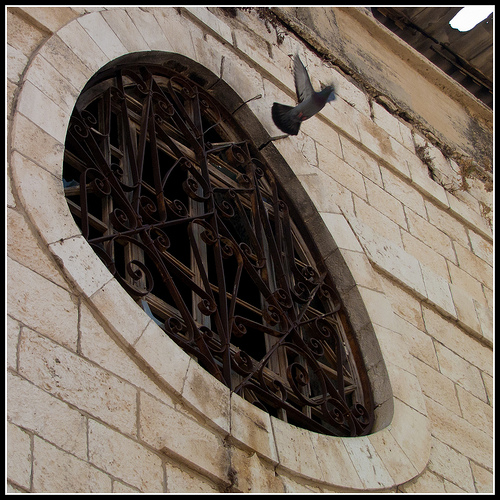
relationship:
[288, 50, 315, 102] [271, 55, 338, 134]
wing belonging to pigeon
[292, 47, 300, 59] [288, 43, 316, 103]
tip belonging to wing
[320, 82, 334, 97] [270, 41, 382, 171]
head belonging to pigeon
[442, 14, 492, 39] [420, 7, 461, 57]
hole in rood tile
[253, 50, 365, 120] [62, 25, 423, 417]
bird flying away window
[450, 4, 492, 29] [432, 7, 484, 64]
sky through a tile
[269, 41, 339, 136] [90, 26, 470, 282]
bird in air